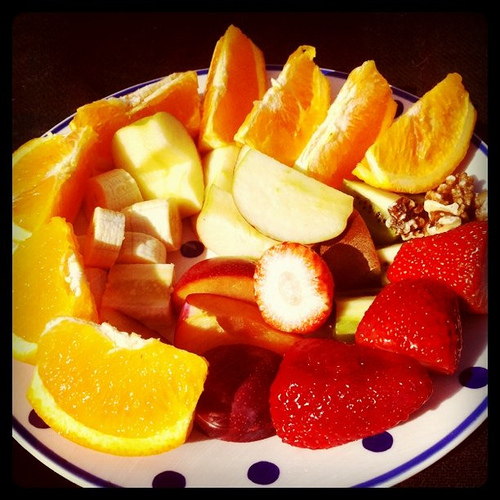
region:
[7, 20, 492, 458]
fruit on the plate.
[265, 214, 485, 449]
the strawberries are red.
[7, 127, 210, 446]
the oranges are orange.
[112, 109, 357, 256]
the apples are sliced.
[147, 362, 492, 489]
blue dots on the plate.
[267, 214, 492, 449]
the strawberries are sliced.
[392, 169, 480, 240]
granola on the plate.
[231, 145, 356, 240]
the apple is white and green.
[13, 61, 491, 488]
a white plate with blue decorations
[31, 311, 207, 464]
a small lemon wedge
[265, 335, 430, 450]
a half a strawberry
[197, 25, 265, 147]
an orange wedge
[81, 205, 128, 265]
a slice of banana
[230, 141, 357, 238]
an apple wedge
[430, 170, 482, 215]
a brown walnut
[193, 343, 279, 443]
the red skin of an apple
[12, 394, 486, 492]
a blue ring around a plate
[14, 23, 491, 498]
Blue and white plate.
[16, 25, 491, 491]
Plate with fruit on it.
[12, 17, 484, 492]
A white plate with blue dots with some food on it.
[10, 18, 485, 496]
Plate covered with fruit and walnuts.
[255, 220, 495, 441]
Strawberries on the plate.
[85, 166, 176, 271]
Sliced bananas on the plate.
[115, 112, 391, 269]
Cored apple quartered on the plate.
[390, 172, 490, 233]
Some shelled walnuts on the plate.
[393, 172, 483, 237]
Some walnuts beside the strawberries.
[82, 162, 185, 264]
Four slices of banana on plate.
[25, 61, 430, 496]
this is a fruit plate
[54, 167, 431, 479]
this is snack food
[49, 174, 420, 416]
this food is healthy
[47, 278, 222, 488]
this is an orange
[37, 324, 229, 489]
the orange is sliced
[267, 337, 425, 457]
this is a strawberry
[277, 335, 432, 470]
the strawberry is sliced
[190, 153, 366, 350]
these are apple slices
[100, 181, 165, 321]
this is banana slices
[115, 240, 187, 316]
the banana is yellow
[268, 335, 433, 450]
half strawberry vertically sliced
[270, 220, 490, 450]
bunch of half strawberries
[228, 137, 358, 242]
a slice of apple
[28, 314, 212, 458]
a slice of orange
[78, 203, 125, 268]
a round slice of banana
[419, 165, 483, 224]
brown walnut piece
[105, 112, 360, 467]
a bunch of red apple slices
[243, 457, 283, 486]
blue dot on white plate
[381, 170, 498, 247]
walnut halves on plate